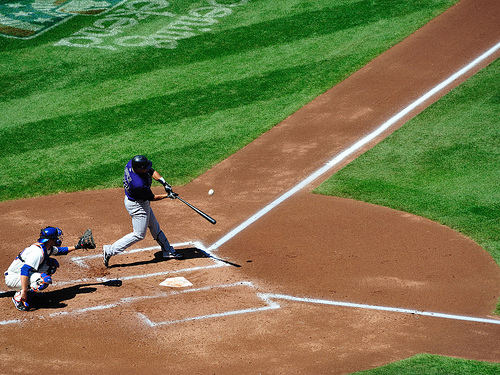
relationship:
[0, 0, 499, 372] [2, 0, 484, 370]
dirt in field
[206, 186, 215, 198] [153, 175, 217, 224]
ball in front of bat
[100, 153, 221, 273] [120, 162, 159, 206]
batter wearing jersey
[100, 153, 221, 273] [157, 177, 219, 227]
batter swinging bat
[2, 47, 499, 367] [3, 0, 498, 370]
lines on baseball field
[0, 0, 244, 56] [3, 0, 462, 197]
design on grass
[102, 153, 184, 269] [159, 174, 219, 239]
batter swinging bat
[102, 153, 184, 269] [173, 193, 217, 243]
batter swinging bat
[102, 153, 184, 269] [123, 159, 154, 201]
batter wearing jersey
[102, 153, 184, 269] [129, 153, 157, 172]
batter wearing helmet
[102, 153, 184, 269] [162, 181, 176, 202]
batter wearing gloves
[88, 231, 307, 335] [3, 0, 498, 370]
chalk lines on baseball field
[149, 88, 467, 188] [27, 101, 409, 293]
green grass and brown dirt on a baseball field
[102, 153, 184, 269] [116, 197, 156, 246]
batter wearing pants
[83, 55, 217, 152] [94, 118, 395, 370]
grass on field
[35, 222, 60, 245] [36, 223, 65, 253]
helmet on head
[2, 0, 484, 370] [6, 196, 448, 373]
field surrounding mound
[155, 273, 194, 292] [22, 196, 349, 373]
diamond in dirt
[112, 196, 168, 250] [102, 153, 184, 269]
uniform on batter